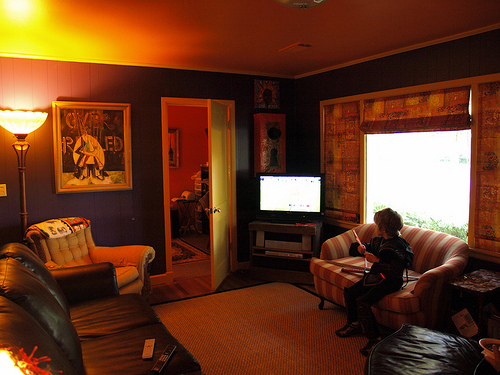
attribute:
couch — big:
[310, 168, 487, 333]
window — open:
[365, 130, 471, 242]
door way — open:
[158, 95, 235, 285]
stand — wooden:
[242, 216, 309, 257]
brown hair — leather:
[15, 246, 140, 357]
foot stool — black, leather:
[360, 318, 491, 373]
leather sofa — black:
[0, 236, 202, 373]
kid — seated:
[333, 194, 416, 360]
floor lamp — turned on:
[1, 93, 55, 258]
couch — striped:
[308, 223, 470, 333]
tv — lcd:
[255, 172, 325, 223]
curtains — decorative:
[315, 72, 498, 253]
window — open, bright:
[359, 128, 471, 247]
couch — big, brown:
[0, 236, 206, 373]